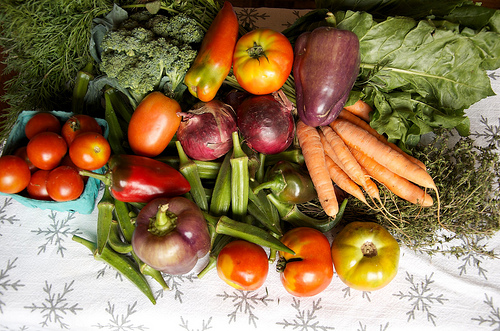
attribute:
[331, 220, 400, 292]
tomato — yellow, plump, green, unripe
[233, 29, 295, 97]
tomato — green, red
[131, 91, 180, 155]
tomato — red, green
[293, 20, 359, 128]
pepper — plum, purple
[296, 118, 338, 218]
carrot — green, orange, thick, long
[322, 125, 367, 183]
carrot — green, orange, thick, long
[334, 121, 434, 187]
carrot — green, orange, thick, long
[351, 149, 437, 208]
carrot — green, orange, thick, long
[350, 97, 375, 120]
carrot — green, orange, thick, long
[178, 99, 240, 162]
onion — red, purple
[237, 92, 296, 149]
onion — red, purple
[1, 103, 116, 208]
container — green, small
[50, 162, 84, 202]
tomato — small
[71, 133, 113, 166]
tomato — small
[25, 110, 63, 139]
tomato — small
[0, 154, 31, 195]
tomato — small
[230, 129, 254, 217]
okra — green, ridged, long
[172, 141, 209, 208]
okra — green, ridged, long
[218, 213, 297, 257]
okra — green, ridged, long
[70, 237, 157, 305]
okra — green, ridged, long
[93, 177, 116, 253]
okra — green, ridged, long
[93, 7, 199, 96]
broccoli — medium head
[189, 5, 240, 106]
pepper — hot, red, reddish, green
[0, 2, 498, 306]
garden — decorative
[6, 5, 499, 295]
vegetables — variety, colored, green, assorted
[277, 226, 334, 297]
tomato — red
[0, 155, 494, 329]
table cloth — white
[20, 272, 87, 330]
snowflakes — grey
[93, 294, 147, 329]
snowflakes — grey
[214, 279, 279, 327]
snowflakes — grey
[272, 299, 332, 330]
snowflakes — grey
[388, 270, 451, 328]
snowflakes — grey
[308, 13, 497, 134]
vegetable — green, leafy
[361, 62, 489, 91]
vein — thick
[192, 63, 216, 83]
spot — green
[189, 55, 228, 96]
spot — yellow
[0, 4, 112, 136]
rosemary — long, curved